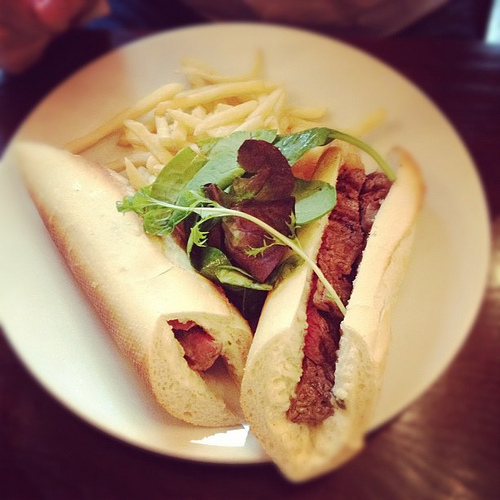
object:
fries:
[166, 106, 203, 129]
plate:
[0, 18, 497, 470]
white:
[308, 45, 356, 114]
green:
[167, 175, 200, 205]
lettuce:
[138, 122, 400, 236]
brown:
[340, 167, 365, 198]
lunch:
[7, 47, 439, 487]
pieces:
[357, 186, 393, 228]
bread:
[10, 132, 265, 430]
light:
[214, 33, 250, 54]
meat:
[317, 218, 364, 279]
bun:
[237, 139, 430, 484]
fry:
[174, 77, 267, 110]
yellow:
[211, 87, 228, 101]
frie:
[61, 80, 187, 157]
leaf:
[144, 205, 180, 237]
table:
[0, 0, 500, 500]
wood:
[0, 0, 500, 499]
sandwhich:
[6, 132, 261, 432]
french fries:
[193, 98, 261, 137]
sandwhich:
[238, 134, 432, 490]